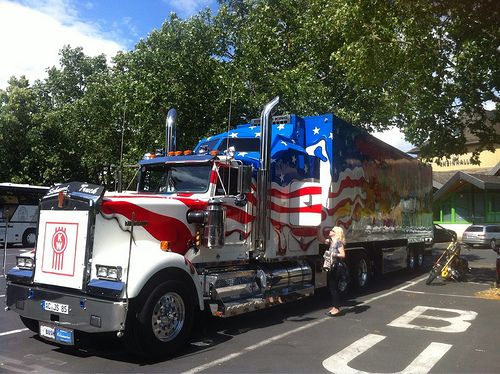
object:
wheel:
[324, 253, 366, 305]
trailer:
[270, 93, 435, 316]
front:
[317, 113, 377, 294]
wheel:
[348, 250, 374, 293]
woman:
[321, 224, 348, 321]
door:
[216, 159, 249, 247]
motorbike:
[425, 236, 471, 286]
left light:
[97, 264, 120, 280]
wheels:
[406, 246, 416, 273]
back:
[408, 156, 443, 273]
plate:
[38, 321, 80, 343]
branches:
[352, 0, 498, 102]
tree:
[0, 73, 42, 181]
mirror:
[236, 164, 256, 197]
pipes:
[163, 107, 183, 193]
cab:
[0, 94, 285, 349]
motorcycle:
[424, 230, 473, 285]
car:
[459, 219, 498, 250]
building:
[402, 107, 499, 246]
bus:
[0, 180, 39, 249]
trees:
[45, 44, 108, 184]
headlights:
[94, 264, 123, 283]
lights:
[207, 148, 218, 157]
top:
[141, 144, 254, 162]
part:
[381, 220, 500, 300]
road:
[432, 231, 498, 337]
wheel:
[127, 271, 198, 363]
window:
[213, 166, 244, 197]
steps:
[209, 288, 265, 317]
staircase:
[207, 259, 270, 321]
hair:
[333, 227, 345, 249]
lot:
[2, 185, 499, 373]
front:
[4, 180, 149, 348]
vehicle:
[5, 93, 441, 350]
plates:
[39, 325, 77, 345]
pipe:
[249, 92, 288, 258]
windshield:
[137, 163, 210, 192]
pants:
[324, 266, 343, 308]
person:
[322, 224, 347, 317]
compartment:
[284, 181, 325, 232]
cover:
[33, 208, 89, 290]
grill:
[30, 181, 106, 294]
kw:
[52, 231, 68, 253]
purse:
[329, 255, 343, 281]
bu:
[320, 301, 479, 373]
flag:
[99, 114, 373, 256]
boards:
[213, 268, 268, 320]